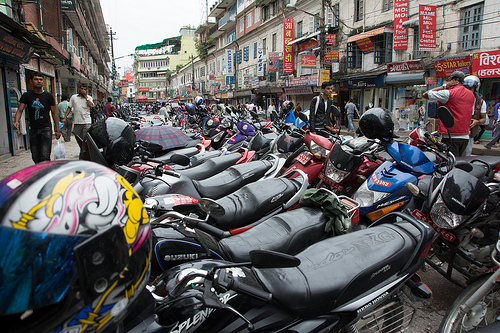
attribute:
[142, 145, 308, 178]
motorcycle — parked, black, dark, large, red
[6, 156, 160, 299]
helmet — black, blue, colorful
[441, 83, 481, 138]
vest — red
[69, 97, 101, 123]
shirt — black, white, red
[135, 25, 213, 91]
building — connected, yellow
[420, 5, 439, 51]
sign — white, red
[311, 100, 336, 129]
coat — black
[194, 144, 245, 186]
seat — black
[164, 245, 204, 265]
logo — suzuki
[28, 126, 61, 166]
pants — black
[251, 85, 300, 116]
umbrella — open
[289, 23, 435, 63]
signs — hanging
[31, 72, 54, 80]
hair — black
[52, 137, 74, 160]
bag — white